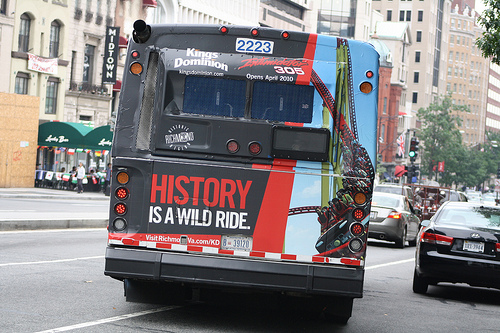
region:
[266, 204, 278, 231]
the bus is red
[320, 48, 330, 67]
the bus is blue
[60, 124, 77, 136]
the awning is green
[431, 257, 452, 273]
the car is black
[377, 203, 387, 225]
the car is silver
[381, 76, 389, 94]
the building is brown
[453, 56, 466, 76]
the building is tan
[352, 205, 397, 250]
the bus is pulling into traffic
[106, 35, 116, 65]
the sign is black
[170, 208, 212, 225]
the words are white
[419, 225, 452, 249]
a tail light on the black car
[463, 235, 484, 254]
the license plate on the black car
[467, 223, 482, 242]
the brand logo on the black car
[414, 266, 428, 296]
the back tire on the black car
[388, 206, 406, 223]
a tail light on the silver car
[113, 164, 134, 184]
a reflector on the back of the bus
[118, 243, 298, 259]
a reflector strip on the back of the bus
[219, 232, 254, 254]
the license plate on the back of the bus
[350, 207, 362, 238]
the brake lights on the back of the bus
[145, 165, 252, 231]
the back of the bus reads "history is a wild ride"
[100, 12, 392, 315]
bus with an advertisement on the back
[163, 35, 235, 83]
advertisement on bus is for King's Dominion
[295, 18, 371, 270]
back of bus features a roller coaster on right side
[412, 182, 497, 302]
a parked black car on the right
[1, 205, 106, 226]
median in the middle of the road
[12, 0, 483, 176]
large tall buildings on the right side of the road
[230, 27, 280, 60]
bus number 2223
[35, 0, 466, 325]
bus is pulling out from the side of road into traffic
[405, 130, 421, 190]
the traffic light is green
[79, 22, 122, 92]
building on the left has a Midtown sign in front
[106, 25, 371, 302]
a bus on the street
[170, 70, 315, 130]
the back window on the bus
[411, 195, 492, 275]
a black car next to the bus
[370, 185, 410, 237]
a silver car in front of the bus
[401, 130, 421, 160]
a green street light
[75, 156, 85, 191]
a man walking on the sidewalk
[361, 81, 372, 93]
a light on the bus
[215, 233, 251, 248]
the license plate on the bus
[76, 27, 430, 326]
back of the bus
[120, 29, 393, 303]
back of the bus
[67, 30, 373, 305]
back of the bus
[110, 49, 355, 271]
back of the bus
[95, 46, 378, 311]
back of the bus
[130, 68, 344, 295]
back of the bus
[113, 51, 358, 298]
back of the bus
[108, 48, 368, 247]
back of the bus